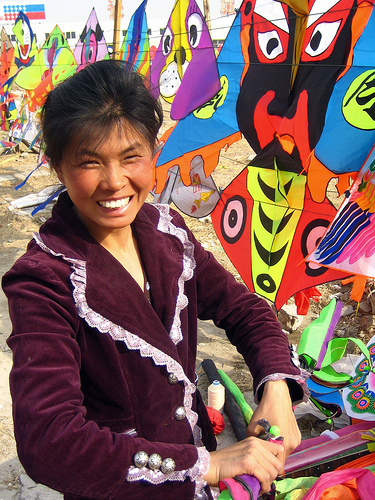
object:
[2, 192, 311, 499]
coat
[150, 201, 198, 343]
white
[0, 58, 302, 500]
woman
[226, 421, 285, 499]
kite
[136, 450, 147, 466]
button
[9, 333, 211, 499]
sleeve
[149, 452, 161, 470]
button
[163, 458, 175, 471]
button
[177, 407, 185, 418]
button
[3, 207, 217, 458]
front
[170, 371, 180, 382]
button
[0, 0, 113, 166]
kites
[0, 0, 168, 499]
left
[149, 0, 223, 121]
kite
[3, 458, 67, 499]
shadow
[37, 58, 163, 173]
hair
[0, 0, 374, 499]
scene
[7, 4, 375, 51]
rope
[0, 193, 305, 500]
dress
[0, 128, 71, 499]
ground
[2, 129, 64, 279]
sand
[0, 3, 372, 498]
picture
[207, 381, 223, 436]
bottle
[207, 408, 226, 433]
twine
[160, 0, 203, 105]
face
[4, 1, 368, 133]
building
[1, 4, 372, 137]
background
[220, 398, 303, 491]
hands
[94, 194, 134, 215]
smile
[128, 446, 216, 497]
trim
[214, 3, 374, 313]
view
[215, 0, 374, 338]
mural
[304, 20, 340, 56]
eye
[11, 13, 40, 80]
cyclops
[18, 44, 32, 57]
lips